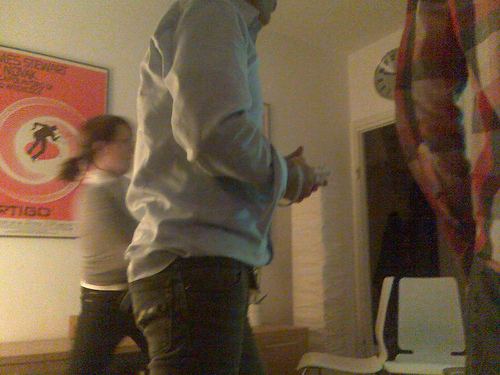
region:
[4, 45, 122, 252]
poste with red background hanging on wall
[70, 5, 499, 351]
three people standing up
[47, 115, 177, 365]
woman wearing gray sweater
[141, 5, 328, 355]
man holding a game controller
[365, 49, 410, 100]
clock hanging above doorway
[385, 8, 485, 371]
man wearing plaid shirt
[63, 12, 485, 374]
three people wearing blue jeans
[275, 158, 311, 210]
white strap of game controller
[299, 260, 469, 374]
two white chairs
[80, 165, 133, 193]
white collar of woman's shirt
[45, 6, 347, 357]
people playing a video game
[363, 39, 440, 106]
a clock over the doorway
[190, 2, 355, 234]
man is holding a game remote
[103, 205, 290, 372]
the man is wearing jeans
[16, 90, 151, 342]
the woman is blurry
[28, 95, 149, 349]
the woman is in motion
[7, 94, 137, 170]
the woman is wearing glasses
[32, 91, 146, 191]
the woman is wearing a ponytail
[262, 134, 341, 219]
the remote is white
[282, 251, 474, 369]
the chairs are empty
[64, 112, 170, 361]
A girl is moving.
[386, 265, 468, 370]
A white chair.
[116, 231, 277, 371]
Blue jeans on a man.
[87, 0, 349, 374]
A man in white is holding something in his hand.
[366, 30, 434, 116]
A clock is hanging on the wall.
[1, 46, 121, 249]
A red poster is hanging on the wall.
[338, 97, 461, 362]
A dark closet.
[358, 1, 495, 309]
A plaid shirt on a man.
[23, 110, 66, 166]
A dark silhouette on a poster.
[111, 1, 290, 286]
A casual blue shirt on a man.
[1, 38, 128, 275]
red and white movie poster on wall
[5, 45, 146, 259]
vertigo movie poster on wall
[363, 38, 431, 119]
silver and black clock on wall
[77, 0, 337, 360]
people playing video games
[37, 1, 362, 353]
people playing nintendo wii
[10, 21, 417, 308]
artwork on white walls in apartment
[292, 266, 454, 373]
plastic white chairs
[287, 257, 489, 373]
two white chairs back to back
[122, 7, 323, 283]
man in gray sweatshirt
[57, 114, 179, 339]
girl playing video games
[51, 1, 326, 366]
a couple playing a game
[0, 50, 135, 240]
a red picture on the wall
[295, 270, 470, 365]
a couple of chairs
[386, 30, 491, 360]
a person watching a game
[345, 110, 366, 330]
a wooden door facing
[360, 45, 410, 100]
a clock over a door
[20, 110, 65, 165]
a man in a picture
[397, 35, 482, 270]
a red and brown shirt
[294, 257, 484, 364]
a couple of white chairs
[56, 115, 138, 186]
a pony tail in a girl hairs